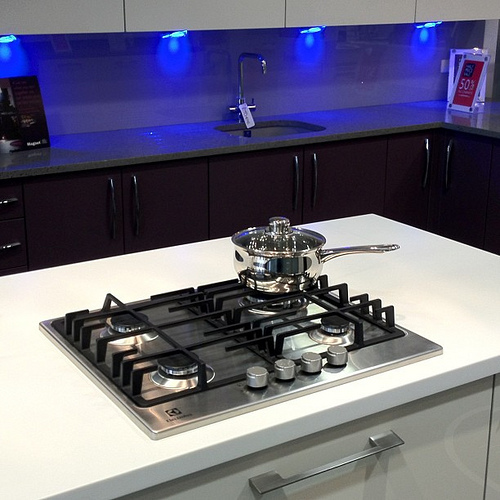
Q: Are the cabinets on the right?
A: No, the cabinets are on the left of the image.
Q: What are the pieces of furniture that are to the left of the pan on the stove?
A: The pieces of furniture are cabinets.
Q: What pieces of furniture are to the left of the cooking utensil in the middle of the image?
A: The pieces of furniture are cabinets.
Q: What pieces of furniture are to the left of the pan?
A: The pieces of furniture are cabinets.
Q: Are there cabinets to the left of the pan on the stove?
A: Yes, there are cabinets to the left of the pan.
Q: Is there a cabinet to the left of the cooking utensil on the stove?
A: Yes, there are cabinets to the left of the pan.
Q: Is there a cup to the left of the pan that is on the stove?
A: No, there are cabinets to the left of the pan.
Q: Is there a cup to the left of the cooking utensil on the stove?
A: No, there are cabinets to the left of the pan.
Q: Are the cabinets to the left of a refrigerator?
A: No, the cabinets are to the left of a pan.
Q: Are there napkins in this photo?
A: No, there are no napkins.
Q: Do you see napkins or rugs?
A: No, there are no napkins or rugs.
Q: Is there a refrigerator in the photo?
A: No, there are no refrigerators.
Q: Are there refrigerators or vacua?
A: No, there are no refrigerators or vacua.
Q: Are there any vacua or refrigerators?
A: No, there are no refrigerators or vacua.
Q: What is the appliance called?
A: The appliance is a stove.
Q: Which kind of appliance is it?
A: The appliance is a stove.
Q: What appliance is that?
A: This is a stove.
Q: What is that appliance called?
A: This is a stove.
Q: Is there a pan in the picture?
A: Yes, there is a pan.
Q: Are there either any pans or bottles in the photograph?
A: Yes, there is a pan.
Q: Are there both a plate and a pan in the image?
A: No, there is a pan but no plates.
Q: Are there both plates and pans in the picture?
A: No, there is a pan but no plates.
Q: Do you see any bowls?
A: No, there are no bowls.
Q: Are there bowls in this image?
A: No, there are no bowls.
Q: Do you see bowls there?
A: No, there are no bowls.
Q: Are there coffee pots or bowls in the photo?
A: No, there are no bowls or coffee pots.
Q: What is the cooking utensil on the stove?
A: The cooking utensil is a pan.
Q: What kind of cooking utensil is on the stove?
A: The cooking utensil is a pan.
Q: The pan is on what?
A: The pan is on the stove.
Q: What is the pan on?
A: The pan is on the stove.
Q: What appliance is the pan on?
A: The pan is on the stove.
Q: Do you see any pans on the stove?
A: Yes, there is a pan on the stove.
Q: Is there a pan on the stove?
A: Yes, there is a pan on the stove.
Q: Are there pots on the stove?
A: No, there is a pan on the stove.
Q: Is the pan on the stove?
A: Yes, the pan is on the stove.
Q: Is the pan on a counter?
A: No, the pan is on the stove.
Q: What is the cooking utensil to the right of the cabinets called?
A: The cooking utensil is a pan.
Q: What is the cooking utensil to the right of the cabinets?
A: The cooking utensil is a pan.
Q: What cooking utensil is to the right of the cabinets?
A: The cooking utensil is a pan.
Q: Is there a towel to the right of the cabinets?
A: No, there is a pan to the right of the cabinets.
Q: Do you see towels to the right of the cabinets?
A: No, there is a pan to the right of the cabinets.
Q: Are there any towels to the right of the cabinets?
A: No, there is a pan to the right of the cabinets.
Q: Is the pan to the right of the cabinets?
A: Yes, the pan is to the right of the cabinets.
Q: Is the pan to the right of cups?
A: No, the pan is to the right of the cabinets.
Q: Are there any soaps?
A: No, there are no soaps.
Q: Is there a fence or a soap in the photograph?
A: No, there are no soaps or fences.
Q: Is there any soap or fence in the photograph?
A: No, there are no soaps or fences.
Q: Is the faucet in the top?
A: Yes, the faucet is in the top of the image.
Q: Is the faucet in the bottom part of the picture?
A: No, the faucet is in the top of the image.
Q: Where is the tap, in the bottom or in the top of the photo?
A: The tap is in the top of the image.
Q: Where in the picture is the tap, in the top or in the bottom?
A: The tap is in the top of the image.